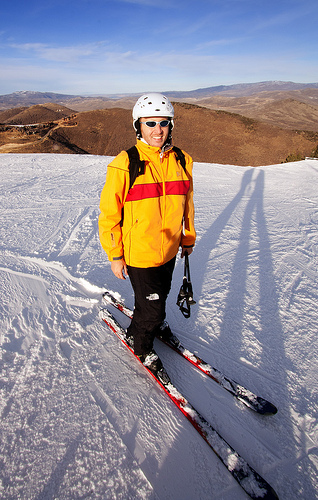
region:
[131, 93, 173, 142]
the white helmet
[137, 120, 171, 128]
the sunglasses on the man's face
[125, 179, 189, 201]
the red stripe on the jacket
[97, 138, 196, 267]
the man's yellow jacket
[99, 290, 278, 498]
the skis on the snow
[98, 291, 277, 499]
the snow on the skis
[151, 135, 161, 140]
the smile on the man's face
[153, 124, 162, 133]
the nose on the man's face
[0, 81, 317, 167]
the mountains in the distance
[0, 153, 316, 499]
the snow on the ground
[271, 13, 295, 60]
This sky is a very bright color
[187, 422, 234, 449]
This ski was a very black color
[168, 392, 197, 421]
This ski is a very red color here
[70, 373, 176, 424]
The snow here is very dark white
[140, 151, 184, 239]
This man is wearing a yellow and red jacket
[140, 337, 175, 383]
This man has a pair of black snow boots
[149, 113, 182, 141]
This man is wearing a pair of sunglasses here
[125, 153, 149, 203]
This man is wearing a backpack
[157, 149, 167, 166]
This man is wearing a coat with a thick zipper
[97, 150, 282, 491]
Jackson Mingus is responsible for taking the photo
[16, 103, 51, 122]
brown hill in the distance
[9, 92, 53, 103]
brown hill in the distance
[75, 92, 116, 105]
brown hill in the distance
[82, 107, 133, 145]
brown hill in the distance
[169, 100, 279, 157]
brown hill in the distance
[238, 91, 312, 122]
brown hill in the distance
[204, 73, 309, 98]
brown hill in the distance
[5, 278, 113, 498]
white snow with fresh tracks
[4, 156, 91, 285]
white snow with fresh tracks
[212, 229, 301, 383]
white snow with fresh tracks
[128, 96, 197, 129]
Person wearing helmet on head.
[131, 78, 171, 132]
Person's helmet is white.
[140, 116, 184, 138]
Sunglasses on person's head.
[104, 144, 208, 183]
Black straps on person's shoulders.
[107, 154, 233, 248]
Person wearing yellow coat.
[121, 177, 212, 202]
Red stripe on yellow jacket.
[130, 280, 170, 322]
Person wearing black pants.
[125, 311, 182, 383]
Person wearing black boots.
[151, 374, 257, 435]
Red and black skis on person's feet.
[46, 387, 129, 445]
Ground is covered in snow.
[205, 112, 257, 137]
brown color on the mountain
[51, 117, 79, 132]
cleared path on the mountain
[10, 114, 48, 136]
blue water in a pond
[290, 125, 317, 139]
green bush on top of the mountain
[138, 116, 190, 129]
blue glasses with blue frame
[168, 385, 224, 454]
patches of snow on skis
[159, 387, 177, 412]
red color on the skis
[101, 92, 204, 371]
skier on red skis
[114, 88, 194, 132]
white helmet on man's head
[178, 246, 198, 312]
black equipment in skier's hand